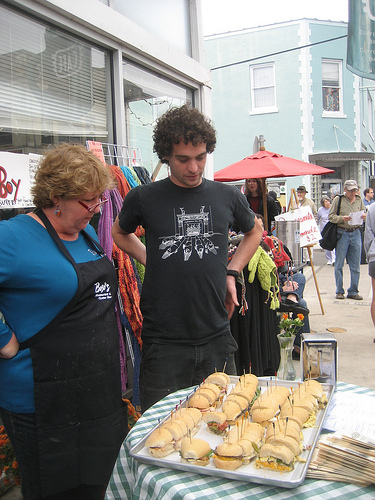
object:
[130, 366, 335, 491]
pan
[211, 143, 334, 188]
umbrella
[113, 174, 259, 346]
shirt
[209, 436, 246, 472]
sandwich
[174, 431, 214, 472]
sandwich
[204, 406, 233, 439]
sandwich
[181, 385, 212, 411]
sandwich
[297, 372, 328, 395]
sandwich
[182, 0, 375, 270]
building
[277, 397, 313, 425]
sandwich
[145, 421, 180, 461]
sandwich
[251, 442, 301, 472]
sandwich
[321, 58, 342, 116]
window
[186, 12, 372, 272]
blue house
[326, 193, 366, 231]
shirt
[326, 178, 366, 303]
man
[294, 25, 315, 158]
trim